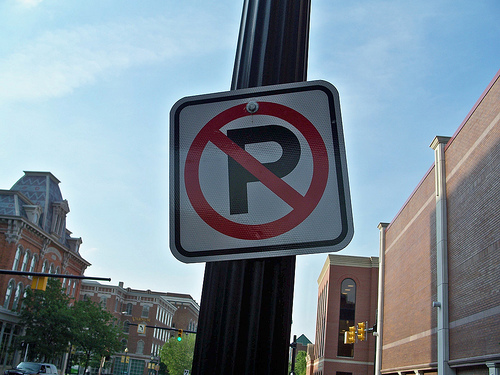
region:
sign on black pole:
[155, 72, 368, 278]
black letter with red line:
[210, 107, 306, 225]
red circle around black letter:
[183, 95, 328, 240]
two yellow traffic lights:
[338, 309, 374, 351]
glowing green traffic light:
[166, 320, 193, 350]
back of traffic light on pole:
[25, 263, 55, 300]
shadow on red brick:
[458, 144, 490, 220]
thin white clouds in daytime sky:
[55, 17, 158, 101]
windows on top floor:
[148, 303, 183, 327]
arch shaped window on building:
[335, 270, 360, 320]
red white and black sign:
[165, 81, 355, 257]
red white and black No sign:
[167, 89, 353, 261]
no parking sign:
[171, 81, 348, 265]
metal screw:
[248, 99, 257, 113]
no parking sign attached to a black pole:
[167, 1, 358, 373]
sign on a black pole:
[166, 1, 356, 368]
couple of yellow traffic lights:
[347, 324, 374, 344]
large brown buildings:
[1, 171, 200, 372]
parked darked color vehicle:
[5, 359, 71, 374]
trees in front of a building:
[0, 167, 127, 372]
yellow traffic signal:
[356, 322, 364, 343]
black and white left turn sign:
[136, 323, 148, 335]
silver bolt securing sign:
[240, 98, 262, 114]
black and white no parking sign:
[169, 97, 349, 251]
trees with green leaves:
[17, 289, 116, 357]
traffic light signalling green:
[176, 329, 183, 341]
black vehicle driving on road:
[3, 361, 60, 373]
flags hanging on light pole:
[119, 354, 131, 365]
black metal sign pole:
[201, 269, 286, 373]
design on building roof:
[11, 175, 51, 198]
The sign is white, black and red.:
[168, 92, 358, 262]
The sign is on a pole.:
[176, 36, 350, 349]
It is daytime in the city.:
[19, 44, 482, 369]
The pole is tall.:
[174, 16, 326, 370]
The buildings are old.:
[9, 179, 199, 369]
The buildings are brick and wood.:
[2, 164, 190, 360]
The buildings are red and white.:
[2, 178, 204, 370]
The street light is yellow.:
[341, 321, 378, 345]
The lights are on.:
[334, 272, 364, 314]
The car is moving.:
[13, 343, 44, 374]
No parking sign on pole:
[171, 83, 361, 276]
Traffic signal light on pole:
[161, 327, 188, 348]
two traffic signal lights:
[339, 318, 388, 351]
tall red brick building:
[10, 163, 90, 373]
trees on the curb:
[17, 277, 94, 373]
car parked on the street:
[1, 343, 65, 373]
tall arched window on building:
[334, 274, 366, 366]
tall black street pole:
[143, 2, 353, 374]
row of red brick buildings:
[23, 269, 205, 374]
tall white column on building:
[422, 132, 464, 374]